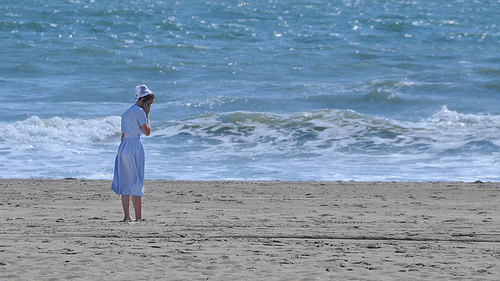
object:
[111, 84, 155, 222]
woman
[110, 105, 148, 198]
dress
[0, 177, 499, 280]
beach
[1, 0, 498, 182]
ocean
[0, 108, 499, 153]
wave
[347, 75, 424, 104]
wave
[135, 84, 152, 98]
hat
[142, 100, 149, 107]
phone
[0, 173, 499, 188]
shore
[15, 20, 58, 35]
wave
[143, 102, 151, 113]
hand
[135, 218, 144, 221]
foot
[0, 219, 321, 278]
sand